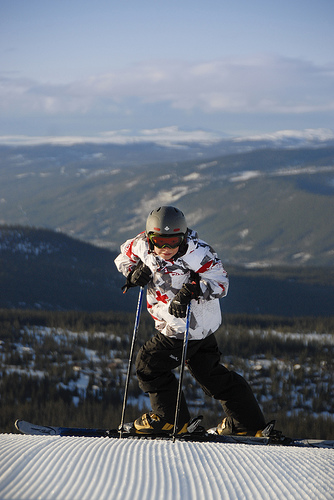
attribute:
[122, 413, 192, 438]
snow boot — yellow, black, blakc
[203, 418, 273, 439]
snow boot — black, yellow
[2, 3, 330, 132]
sky — blue, cloudy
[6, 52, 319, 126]
clouds — low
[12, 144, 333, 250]
mountains — snowy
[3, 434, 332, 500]
snow — white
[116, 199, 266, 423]
person — standing, boy, skating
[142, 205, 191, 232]
helmet — gray, black, blacky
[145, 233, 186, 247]
goggles — tinted, red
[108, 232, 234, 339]
jacket — white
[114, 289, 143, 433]
pole — black, blue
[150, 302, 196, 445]
stick — thin, long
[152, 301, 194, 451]
ski pole — black, blue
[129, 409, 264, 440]
ski boots — black, yellow